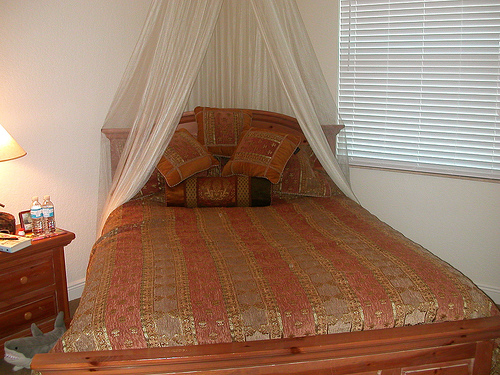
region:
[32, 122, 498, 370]
Wood bed in a bedroom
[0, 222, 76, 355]
Night stand next to the bed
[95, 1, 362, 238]
Mosquito net over the bed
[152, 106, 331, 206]
Pillows on the bed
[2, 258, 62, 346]
Drawers on the night stand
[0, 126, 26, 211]
Lamp on the night stand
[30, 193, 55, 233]
Two bottles of water on the night stand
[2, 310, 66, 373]
Stuffed whale on the floor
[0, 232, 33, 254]
Book on the night stand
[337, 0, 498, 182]
Blinds on the window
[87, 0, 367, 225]
sheer white canopy over bed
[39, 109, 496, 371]
oak bed frame in room corner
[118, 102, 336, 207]
orange and brown throw pillows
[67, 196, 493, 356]
orange and brown detailed comforter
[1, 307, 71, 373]
shark pillow on floor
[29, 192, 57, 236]
two bottles of generic filtered water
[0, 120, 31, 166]
lampshade with lit bulb inside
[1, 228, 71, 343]
oak nightstand beside bed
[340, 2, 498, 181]
closed plain white blinds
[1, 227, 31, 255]
closed book on night stand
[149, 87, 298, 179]
three square pillows on bed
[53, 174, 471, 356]
orange and tan bedspread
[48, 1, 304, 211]
white curtain over bed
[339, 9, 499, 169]
white blinds near bed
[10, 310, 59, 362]
stuffed animal on floor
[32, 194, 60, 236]
water bottles next to bed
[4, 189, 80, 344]
water bottles on table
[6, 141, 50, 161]
white lamp on table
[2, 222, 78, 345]
table is red and wooden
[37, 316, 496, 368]
bed has wooden feet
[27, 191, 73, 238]
two plastic water bottles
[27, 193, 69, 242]
two clear water bottles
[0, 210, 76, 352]
a wooden night stand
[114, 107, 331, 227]
several decorative pillows on a bed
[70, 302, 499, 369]
a wooden foot board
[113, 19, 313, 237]
a white net hanging over a bed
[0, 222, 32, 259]
a book on a night stand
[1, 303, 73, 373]
a stuffed shark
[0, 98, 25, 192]
a white lamp shade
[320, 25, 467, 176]
a white blind over a window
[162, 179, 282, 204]
circular pillow on bed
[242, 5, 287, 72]
white canopy behind bed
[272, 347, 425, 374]
foot of the bed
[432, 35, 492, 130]
white blinds in bedroom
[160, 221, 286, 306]
comforter on the bed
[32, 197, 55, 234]
bottles of water on stand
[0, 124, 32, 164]
part of the lampshade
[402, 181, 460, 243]
part of the wall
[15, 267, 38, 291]
knob of the nightstand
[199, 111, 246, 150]
square pillow on bed